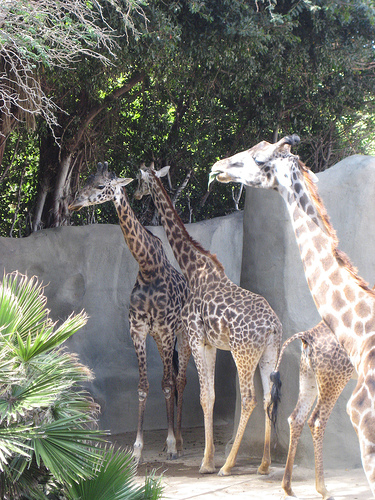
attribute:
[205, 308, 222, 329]
spot — dark brown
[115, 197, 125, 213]
fur — dark brown, spotted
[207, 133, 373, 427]
giraffe — chewing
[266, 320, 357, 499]
baby giraffe — baby 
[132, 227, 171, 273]
spots — dark brown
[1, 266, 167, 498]
plants — green, small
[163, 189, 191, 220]
fur — dark brown, spotted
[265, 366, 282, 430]
tail — black, frizzy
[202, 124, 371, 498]
giraffe — small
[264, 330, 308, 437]
tail — black